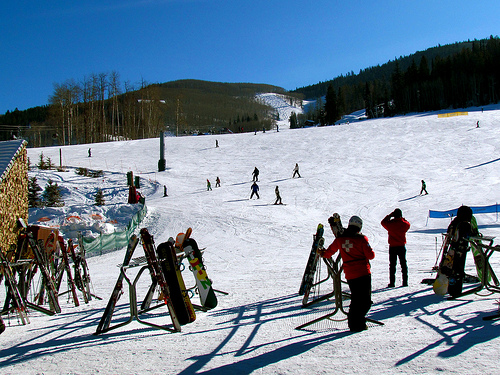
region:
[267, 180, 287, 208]
skier in snow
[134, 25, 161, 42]
white clouds in blue sky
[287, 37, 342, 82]
white clouds in blue sky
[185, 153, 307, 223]
skiers on snowy slope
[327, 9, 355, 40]
white clouds in blue sky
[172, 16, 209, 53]
white clouds in blue sky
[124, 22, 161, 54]
white clouds in blue sky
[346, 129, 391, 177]
Snow capped mountain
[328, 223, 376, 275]
Red jacket in the photo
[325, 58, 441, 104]
Trees growing in the background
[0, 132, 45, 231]
House in the background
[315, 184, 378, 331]
A man standing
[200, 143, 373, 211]
People on ice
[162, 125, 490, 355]
many people on snow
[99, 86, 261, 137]
tall and bare trees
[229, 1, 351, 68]
blue and clear sky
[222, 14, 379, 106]
no clouds in sky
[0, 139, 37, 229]
brown building near people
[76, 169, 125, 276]
green wall near building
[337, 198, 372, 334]
person has dark pants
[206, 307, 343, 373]
long shadows on snow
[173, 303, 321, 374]
black shadows on white snow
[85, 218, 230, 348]
rack of snowboards and skis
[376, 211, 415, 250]
red winter jacket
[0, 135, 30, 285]
rock wall on side of snow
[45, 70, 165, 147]
tall leafless brown tree bordering white snow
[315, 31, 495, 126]
tall line of evergreen trees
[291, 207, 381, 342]
person in red jacket leaning on rack of skis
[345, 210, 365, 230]
hat on person standing in snow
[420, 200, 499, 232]
blue banner on ground in snow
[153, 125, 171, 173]
black upright pole in snow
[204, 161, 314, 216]
skiers on slope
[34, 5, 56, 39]
white clouds in blue sky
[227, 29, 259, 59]
white clouds in blue sky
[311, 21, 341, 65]
white clouds in blue sky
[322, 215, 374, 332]
person on the snowy ski slope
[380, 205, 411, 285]
person on the snowy ski slope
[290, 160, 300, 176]
person on the snowy ski slope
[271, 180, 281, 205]
person on the snowy ski slope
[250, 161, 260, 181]
person on the snowy ski slope